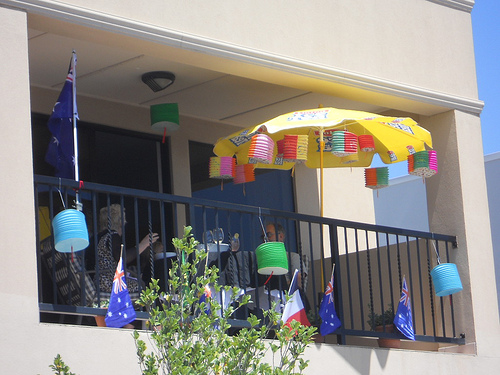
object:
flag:
[44, 51, 78, 185]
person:
[261, 218, 303, 289]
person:
[93, 203, 160, 294]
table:
[152, 243, 230, 290]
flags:
[391, 274, 415, 341]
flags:
[277, 268, 312, 341]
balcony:
[27, 12, 479, 356]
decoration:
[51, 208, 91, 263]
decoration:
[255, 240, 290, 284]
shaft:
[319, 129, 324, 294]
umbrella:
[208, 107, 435, 301]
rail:
[35, 173, 466, 345]